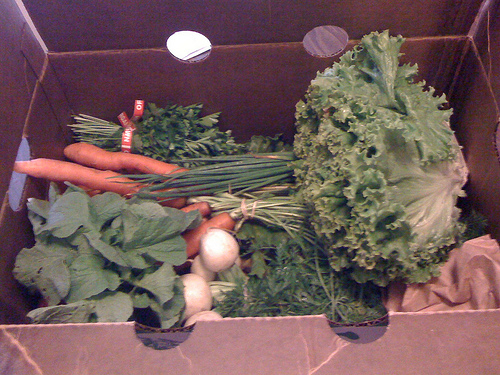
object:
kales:
[16, 195, 182, 327]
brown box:
[3, 0, 495, 373]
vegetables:
[288, 30, 470, 285]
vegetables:
[16, 192, 247, 327]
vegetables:
[64, 95, 243, 184]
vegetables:
[18, 144, 302, 259]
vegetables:
[243, 222, 387, 319]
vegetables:
[37, 71, 464, 317]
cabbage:
[296, 31, 494, 270]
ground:
[411, 163, 431, 194]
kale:
[131, 210, 184, 271]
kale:
[51, 208, 100, 255]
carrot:
[63, 146, 184, 178]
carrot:
[9, 157, 146, 192]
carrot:
[155, 189, 185, 206]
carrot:
[180, 197, 211, 217]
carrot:
[173, 210, 233, 255]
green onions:
[100, 150, 302, 212]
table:
[18, 7, 497, 372]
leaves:
[15, 189, 200, 293]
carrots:
[11, 140, 185, 197]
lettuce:
[287, 30, 477, 282]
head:
[296, 27, 471, 110]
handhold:
[6, 132, 35, 214]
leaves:
[290, 23, 417, 288]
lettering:
[120, 118, 138, 158]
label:
[105, 73, 186, 154]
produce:
[68, 92, 252, 164]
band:
[110, 96, 146, 150]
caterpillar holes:
[27, 265, 50, 297]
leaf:
[10, 247, 72, 309]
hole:
[166, 30, 214, 67]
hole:
[302, 20, 349, 60]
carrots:
[12, 143, 243, 235]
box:
[0, 3, 497, 372]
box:
[4, 33, 499, 348]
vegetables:
[61, 114, 491, 321]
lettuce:
[285, 80, 496, 249]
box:
[18, 158, 486, 375]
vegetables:
[63, 192, 492, 375]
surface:
[37, 19, 417, 48]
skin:
[20, 137, 200, 215]